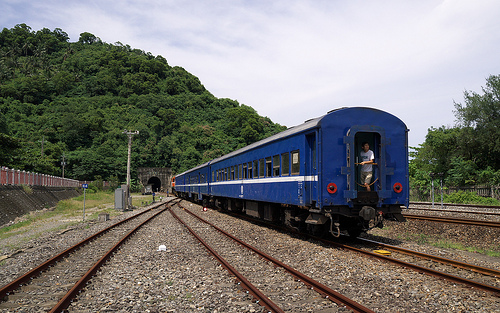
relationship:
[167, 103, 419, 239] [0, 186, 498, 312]
train on tracks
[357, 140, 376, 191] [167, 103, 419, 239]
man on train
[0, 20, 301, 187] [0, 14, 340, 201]
trees on hill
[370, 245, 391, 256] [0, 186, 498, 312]
something on tracks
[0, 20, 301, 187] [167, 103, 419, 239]
trees behind train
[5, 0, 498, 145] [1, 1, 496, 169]
clouds in sky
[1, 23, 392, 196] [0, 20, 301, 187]
leaves on leaves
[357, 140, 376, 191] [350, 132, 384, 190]
man at door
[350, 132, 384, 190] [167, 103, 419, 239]
door on train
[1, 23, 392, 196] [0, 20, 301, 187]
leaves on trees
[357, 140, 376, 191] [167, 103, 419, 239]
man riding train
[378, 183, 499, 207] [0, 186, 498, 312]
fence around tracks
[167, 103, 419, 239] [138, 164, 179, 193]
train entering tunnel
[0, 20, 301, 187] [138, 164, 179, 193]
trees covering tunnel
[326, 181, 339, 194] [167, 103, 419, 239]
headlight on train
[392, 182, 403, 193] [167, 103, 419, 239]
headlight on train